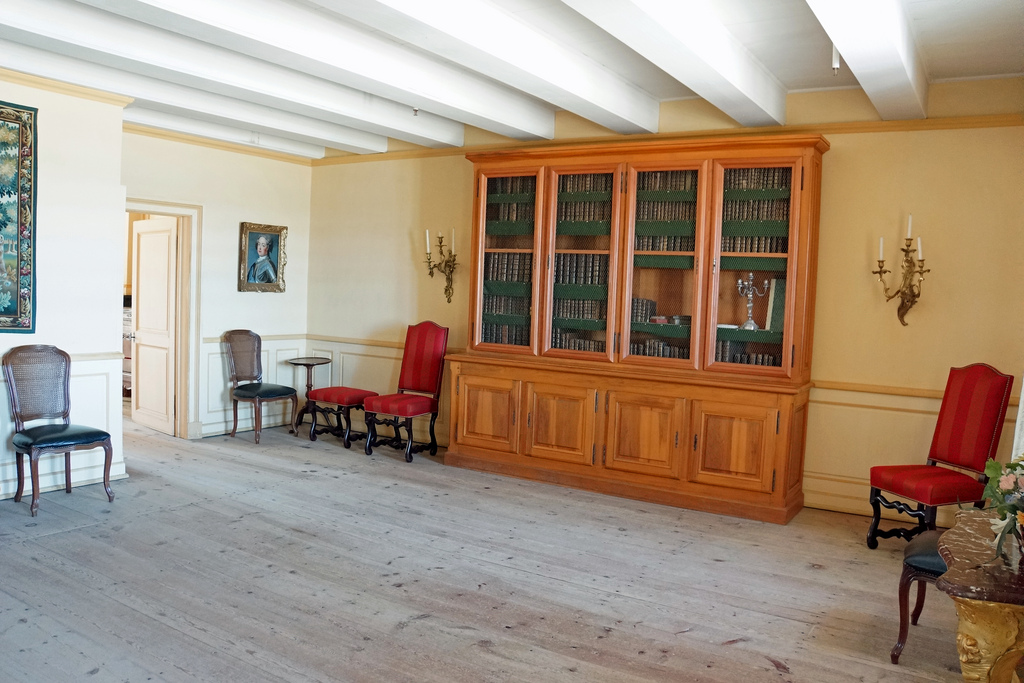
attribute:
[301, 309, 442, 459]
stool — red, black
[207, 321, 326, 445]
chair — black, wooden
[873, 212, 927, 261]
candles — white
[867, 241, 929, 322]
sconce — wall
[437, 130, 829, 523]
bookcase — wooden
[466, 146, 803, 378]
doors — glass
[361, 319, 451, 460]
chair — fabric, red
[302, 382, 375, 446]
ottoman — red, fabric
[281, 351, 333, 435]
table — dark, brown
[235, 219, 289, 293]
portrait — painting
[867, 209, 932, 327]
candle holder — golden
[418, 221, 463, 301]
candle holder — golden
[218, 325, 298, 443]
chair — brown, black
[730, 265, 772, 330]
candelabra — silver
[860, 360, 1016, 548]
chair — red, fabric, black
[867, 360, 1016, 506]
cushions — red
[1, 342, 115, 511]
chair — black, brown, wooden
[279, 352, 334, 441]
table — small, accent, round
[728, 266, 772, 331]
holder — ornate, candle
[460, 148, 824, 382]
book case — wooden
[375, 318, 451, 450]
chair — black, red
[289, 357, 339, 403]
table — wooden, small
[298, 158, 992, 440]
wall — yellow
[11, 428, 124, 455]
seat — black, leather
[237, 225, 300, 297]
frame — gilt